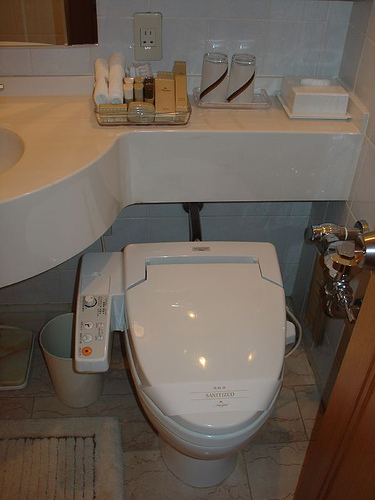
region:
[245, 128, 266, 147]
edge of a sink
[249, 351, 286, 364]
part of a toilet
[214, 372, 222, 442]
part of a toilet seat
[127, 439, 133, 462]
part of a floor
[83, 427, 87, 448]
edge of a mat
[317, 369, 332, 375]
edge of a wall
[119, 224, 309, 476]
White commode in bathroom.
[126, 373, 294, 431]
White strip indicating commode has been santitized.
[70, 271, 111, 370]
Controls knob and buttons for commode.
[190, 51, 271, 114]
Two water glasses turned down in plastic tray.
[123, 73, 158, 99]
Small bottles of shampoo and hair conditioner.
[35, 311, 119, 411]
Beige trash can in bathroom.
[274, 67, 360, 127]
Tissue box on tray on counter.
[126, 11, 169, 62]
Electrical outlet on bathroom wall.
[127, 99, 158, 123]
Bar of soap in plastic tray.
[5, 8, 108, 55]
Edge of mirror over bathroom sink.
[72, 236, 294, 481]
white electric toilet seat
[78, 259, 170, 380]
buttons next to toilet seat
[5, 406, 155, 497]
thick white bathroom rug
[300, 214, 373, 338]
chrome flushing toilet handle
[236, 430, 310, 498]
white cracked tile floor style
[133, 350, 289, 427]
white paper on tip of toilet seat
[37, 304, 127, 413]
white toilet trash can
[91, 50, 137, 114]
two white folded hand towels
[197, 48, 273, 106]
two glass cups on counter top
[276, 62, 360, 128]
white paper towel container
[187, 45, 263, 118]
Two glasses on a tray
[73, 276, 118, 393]
Buttons and controls on a toilet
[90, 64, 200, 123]
Towels soaps and shampoos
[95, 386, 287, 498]
Marble tile on the floor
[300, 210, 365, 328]
chrome plumbing for the toilet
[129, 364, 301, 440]
Papers seal over seat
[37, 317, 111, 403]
White wastebasket in bathroom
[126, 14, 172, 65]
Electrical outlet on wall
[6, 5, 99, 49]
Mirror in bathroom reflecting wall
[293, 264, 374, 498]
Brown wooden door is open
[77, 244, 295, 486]
a closed toilet seat lid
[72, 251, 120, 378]
electronic toilet bowl controls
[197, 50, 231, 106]
a striped water glass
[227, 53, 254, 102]
a striped water glass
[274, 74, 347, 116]
a white tissue container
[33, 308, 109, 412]
a white trash can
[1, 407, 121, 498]
a white bath mat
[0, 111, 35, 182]
a bathroom sink basin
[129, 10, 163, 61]
an electrical wall switch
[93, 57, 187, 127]
a basket of complimentary soaps